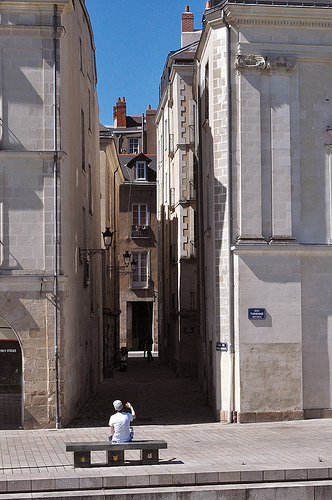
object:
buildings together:
[85, 99, 190, 387]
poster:
[248, 308, 266, 320]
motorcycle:
[117, 347, 131, 373]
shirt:
[108, 412, 134, 444]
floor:
[66, 354, 217, 423]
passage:
[84, 346, 209, 423]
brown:
[121, 196, 128, 232]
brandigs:
[69, 449, 161, 468]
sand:
[141, 448, 159, 465]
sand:
[107, 450, 124, 466]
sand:
[74, 451, 91, 468]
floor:
[0, 417, 331, 480]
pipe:
[51, 3, 61, 427]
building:
[0, 0, 102, 427]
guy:
[108, 400, 136, 443]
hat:
[113, 399, 123, 411]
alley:
[78, 329, 208, 402]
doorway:
[125, 300, 157, 354]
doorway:
[0, 313, 24, 430]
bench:
[66, 439, 168, 467]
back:
[113, 411, 131, 439]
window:
[136, 159, 146, 179]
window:
[129, 138, 139, 153]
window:
[132, 203, 148, 227]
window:
[130, 250, 149, 289]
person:
[143, 330, 154, 362]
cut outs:
[91, 450, 107, 465]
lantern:
[102, 227, 115, 249]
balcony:
[129, 273, 150, 289]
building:
[101, 93, 167, 369]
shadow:
[256, 315, 274, 327]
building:
[197, 0, 332, 422]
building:
[148, 4, 208, 395]